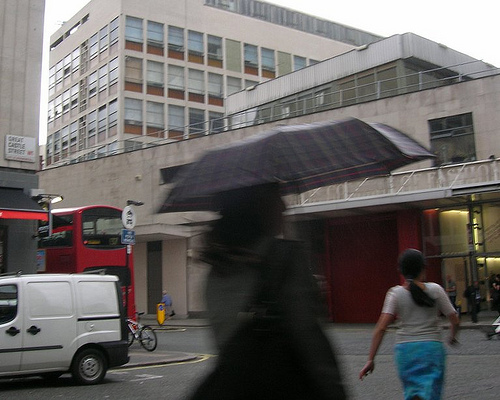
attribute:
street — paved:
[0, 316, 498, 398]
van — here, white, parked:
[0, 272, 129, 383]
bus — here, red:
[39, 205, 139, 339]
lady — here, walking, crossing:
[201, 186, 349, 400]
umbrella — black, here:
[156, 114, 434, 214]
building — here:
[48, 2, 387, 171]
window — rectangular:
[127, 15, 145, 53]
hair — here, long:
[196, 189, 281, 274]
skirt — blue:
[397, 339, 446, 400]